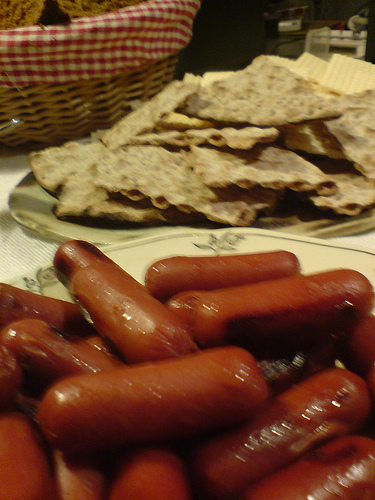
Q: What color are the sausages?
A: Red.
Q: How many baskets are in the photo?
A: One.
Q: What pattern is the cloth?
A: Plaid.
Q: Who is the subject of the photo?
A: The sausages.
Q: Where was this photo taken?
A: At a table.